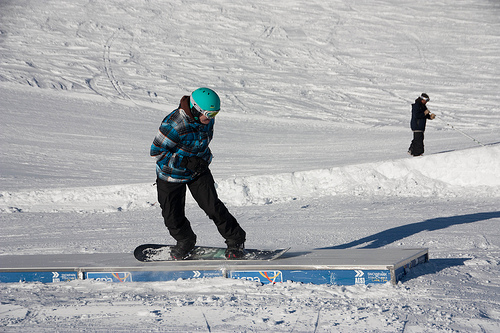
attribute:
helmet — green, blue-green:
[188, 87, 222, 116]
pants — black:
[154, 169, 247, 244]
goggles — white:
[202, 108, 219, 120]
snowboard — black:
[132, 242, 291, 261]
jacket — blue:
[149, 108, 216, 182]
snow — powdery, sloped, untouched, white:
[1, 1, 500, 333]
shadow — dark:
[313, 211, 500, 249]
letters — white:
[354, 277, 365, 285]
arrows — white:
[352, 269, 364, 279]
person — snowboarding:
[148, 86, 247, 258]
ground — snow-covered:
[1, 1, 499, 332]